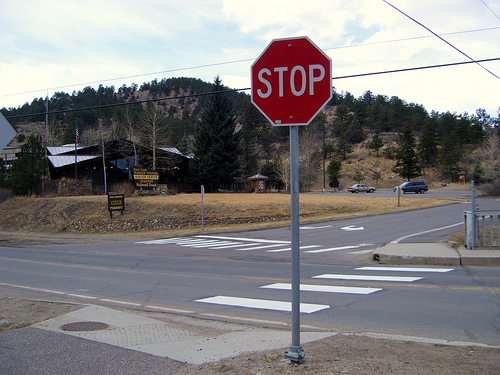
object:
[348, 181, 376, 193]
cars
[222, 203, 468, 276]
road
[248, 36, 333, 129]
sign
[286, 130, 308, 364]
post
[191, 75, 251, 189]
tree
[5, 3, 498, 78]
sky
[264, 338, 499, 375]
ground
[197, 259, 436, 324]
cross walk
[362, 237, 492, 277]
curb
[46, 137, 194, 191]
building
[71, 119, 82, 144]
flag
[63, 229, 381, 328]
intersection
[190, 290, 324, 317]
stripes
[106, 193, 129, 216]
sign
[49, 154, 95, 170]
roofing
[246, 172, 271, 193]
kiosk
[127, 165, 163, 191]
sign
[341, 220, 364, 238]
arrow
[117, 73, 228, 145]
hill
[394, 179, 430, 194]
car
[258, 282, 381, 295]
line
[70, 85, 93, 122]
trees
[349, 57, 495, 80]
wire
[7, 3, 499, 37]
clouds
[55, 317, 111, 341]
manhole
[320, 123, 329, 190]
pole